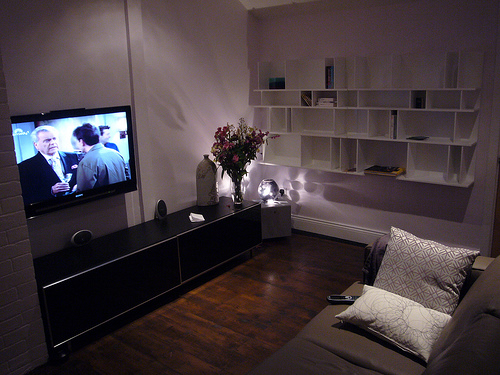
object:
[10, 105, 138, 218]
television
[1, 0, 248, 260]
wall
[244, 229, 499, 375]
couch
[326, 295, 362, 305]
remote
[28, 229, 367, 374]
floor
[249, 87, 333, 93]
shelves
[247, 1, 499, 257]
wall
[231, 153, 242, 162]
flowers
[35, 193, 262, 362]
stand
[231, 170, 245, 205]
vase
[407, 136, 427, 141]
book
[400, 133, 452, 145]
shelf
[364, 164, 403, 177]
book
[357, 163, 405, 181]
shelf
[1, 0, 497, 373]
living room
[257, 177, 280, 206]
vase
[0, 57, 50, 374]
wall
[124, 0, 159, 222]
trim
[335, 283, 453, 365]
pillow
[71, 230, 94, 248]
speaker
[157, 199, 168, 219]
speaker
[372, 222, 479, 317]
pillow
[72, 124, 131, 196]
men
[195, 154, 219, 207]
pottery vase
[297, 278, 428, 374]
cushion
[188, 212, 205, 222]
book